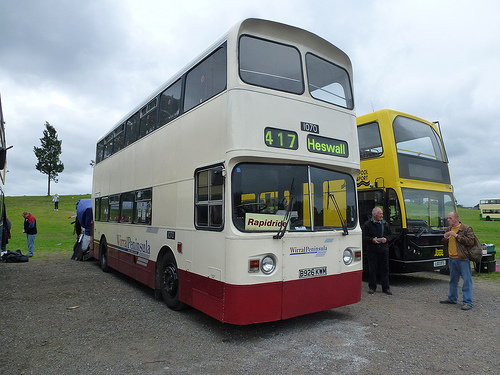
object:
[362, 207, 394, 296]
man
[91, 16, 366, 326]
bus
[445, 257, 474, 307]
jeans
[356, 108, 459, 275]
bus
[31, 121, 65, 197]
tree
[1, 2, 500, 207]
clouds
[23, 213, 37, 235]
jacket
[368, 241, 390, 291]
pants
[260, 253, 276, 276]
light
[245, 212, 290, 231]
sign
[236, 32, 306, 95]
window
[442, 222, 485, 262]
jacket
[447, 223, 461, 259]
shirt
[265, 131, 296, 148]
number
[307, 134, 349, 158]
destination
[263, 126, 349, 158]
display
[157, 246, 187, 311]
wheel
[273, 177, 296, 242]
wiper